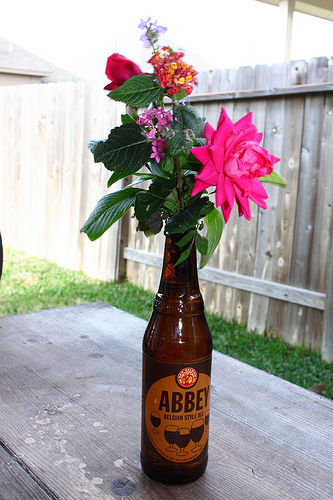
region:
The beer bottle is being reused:
[140, 230, 211, 487]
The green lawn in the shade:
[228, 323, 262, 355]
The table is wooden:
[24, 340, 106, 423]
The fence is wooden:
[236, 228, 309, 320]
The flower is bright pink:
[186, 105, 278, 222]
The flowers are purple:
[137, 14, 165, 43]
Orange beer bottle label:
[141, 365, 206, 461]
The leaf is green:
[75, 184, 135, 238]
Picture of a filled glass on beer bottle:
[187, 417, 204, 453]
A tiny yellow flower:
[170, 61, 178, 70]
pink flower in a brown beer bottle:
[189, 99, 284, 224]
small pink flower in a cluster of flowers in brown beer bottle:
[147, 143, 162, 161]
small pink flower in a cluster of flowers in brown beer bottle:
[141, 126, 159, 142]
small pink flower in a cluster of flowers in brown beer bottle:
[137, 114, 156, 125]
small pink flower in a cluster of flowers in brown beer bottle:
[153, 115, 172, 125]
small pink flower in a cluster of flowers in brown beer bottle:
[151, 107, 168, 115]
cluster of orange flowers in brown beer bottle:
[148, 43, 198, 101]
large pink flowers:
[100, 47, 151, 96]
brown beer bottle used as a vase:
[137, 216, 212, 483]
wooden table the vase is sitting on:
[4, 294, 332, 499]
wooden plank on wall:
[303, 70, 329, 356]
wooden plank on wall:
[248, 60, 297, 355]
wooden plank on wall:
[60, 76, 99, 287]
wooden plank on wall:
[31, 72, 70, 283]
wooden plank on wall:
[9, 80, 54, 273]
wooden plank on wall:
[228, 60, 261, 120]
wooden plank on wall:
[195, 55, 233, 112]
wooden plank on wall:
[215, 278, 241, 319]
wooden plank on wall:
[247, 284, 274, 330]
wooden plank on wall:
[269, 288, 302, 346]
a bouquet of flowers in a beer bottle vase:
[79, 24, 285, 492]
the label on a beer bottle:
[138, 351, 210, 469]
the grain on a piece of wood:
[24, 348, 91, 432]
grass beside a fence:
[220, 304, 290, 368]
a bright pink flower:
[190, 107, 275, 223]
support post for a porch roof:
[270, 2, 296, 65]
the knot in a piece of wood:
[88, 350, 103, 359]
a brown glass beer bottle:
[139, 225, 212, 483]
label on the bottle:
[152, 385, 211, 472]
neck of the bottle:
[139, 222, 219, 297]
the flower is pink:
[185, 127, 271, 206]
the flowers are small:
[90, 18, 177, 146]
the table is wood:
[252, 405, 293, 480]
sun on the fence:
[2, 123, 70, 228]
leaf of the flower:
[94, 74, 172, 108]